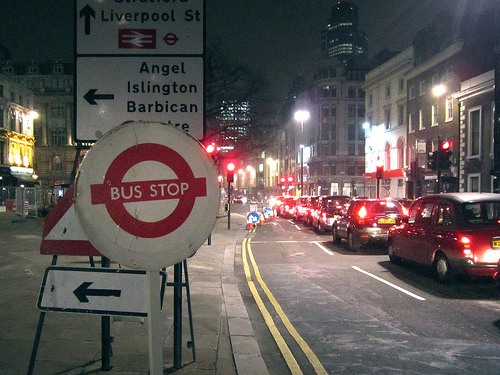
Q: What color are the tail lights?
A: Red.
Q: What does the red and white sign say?
A: Bus Stop.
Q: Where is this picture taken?
A: The street in London.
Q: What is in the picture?
A: A line of cars.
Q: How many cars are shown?
A: Ten.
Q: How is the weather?
A: Clear.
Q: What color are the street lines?
A: Yellow.